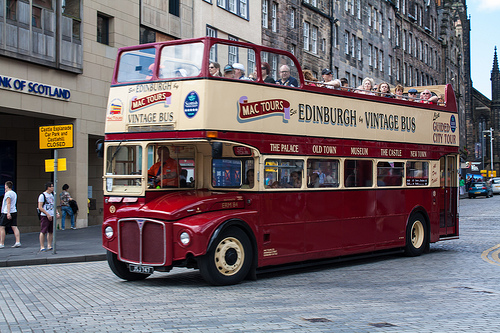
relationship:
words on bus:
[237, 91, 423, 139] [103, 35, 457, 268]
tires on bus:
[391, 202, 439, 259] [103, 35, 457, 268]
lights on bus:
[100, 224, 189, 248] [103, 35, 457, 268]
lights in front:
[100, 224, 189, 248] [108, 40, 207, 280]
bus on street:
[103, 35, 457, 268] [0, 191, 499, 332]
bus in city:
[103, 35, 457, 268] [1, 0, 499, 333]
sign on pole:
[36, 120, 77, 152] [50, 149, 58, 259]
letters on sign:
[42, 126, 67, 146] [36, 120, 77, 152]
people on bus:
[133, 58, 447, 108] [103, 35, 457, 268]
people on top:
[133, 58, 447, 108] [110, 37, 459, 109]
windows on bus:
[263, 156, 433, 191] [103, 35, 457, 268]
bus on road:
[103, 35, 457, 268] [0, 191, 499, 332]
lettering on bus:
[298, 100, 419, 136] [103, 35, 457, 268]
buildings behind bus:
[0, 2, 499, 230] [103, 35, 457, 268]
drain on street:
[457, 282, 489, 299] [0, 191, 499, 332]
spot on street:
[306, 311, 332, 326] [0, 191, 499, 332]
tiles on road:
[2, 195, 497, 326] [0, 191, 499, 332]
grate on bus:
[115, 215, 169, 268] [103, 35, 457, 268]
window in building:
[93, 8, 116, 49] [0, 2, 499, 230]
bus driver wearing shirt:
[148, 144, 179, 191] [146, 160, 184, 188]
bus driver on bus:
[148, 144, 179, 191] [103, 35, 457, 268]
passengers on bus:
[133, 58, 447, 108] [103, 35, 457, 268]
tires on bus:
[406, 210, 427, 255] [103, 35, 457, 268]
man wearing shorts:
[35, 182, 61, 254] [38, 212, 55, 236]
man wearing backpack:
[35, 182, 61, 254] [32, 190, 48, 219]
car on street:
[471, 182, 489, 199] [0, 191, 499, 332]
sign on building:
[1, 73, 73, 106] [0, 2, 499, 230]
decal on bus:
[183, 89, 200, 119] [103, 35, 457, 268]